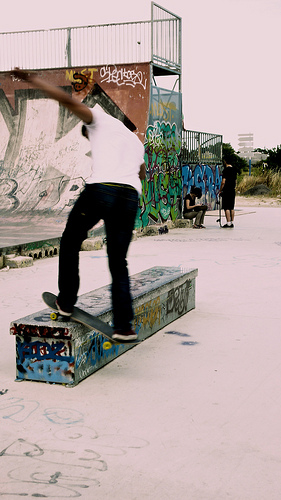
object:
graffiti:
[0, 178, 88, 216]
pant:
[56, 181, 138, 327]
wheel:
[103, 340, 112, 350]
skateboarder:
[10, 65, 146, 347]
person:
[182, 184, 206, 229]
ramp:
[0, 64, 146, 232]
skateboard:
[40, 290, 139, 346]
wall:
[183, 161, 224, 213]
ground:
[0, 186, 281, 500]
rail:
[0, 5, 182, 73]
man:
[14, 64, 147, 341]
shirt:
[85, 102, 144, 195]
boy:
[11, 66, 146, 341]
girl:
[184, 185, 205, 229]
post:
[151, 1, 184, 70]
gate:
[151, 85, 182, 226]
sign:
[238, 132, 253, 156]